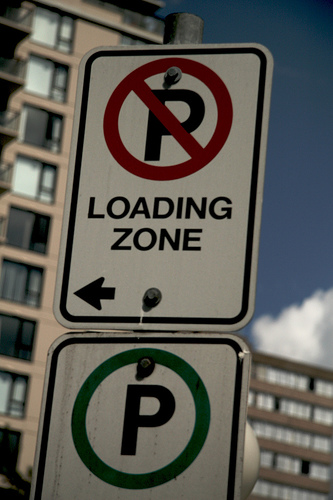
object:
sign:
[25, 318, 265, 500]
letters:
[81, 184, 242, 264]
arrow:
[72, 271, 118, 312]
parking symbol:
[64, 341, 220, 500]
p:
[111, 371, 180, 466]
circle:
[65, 336, 220, 495]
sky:
[155, 1, 333, 380]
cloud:
[242, 283, 333, 373]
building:
[0, 0, 332, 499]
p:
[137, 81, 210, 170]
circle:
[98, 51, 238, 188]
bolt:
[138, 357, 153, 370]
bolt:
[163, 66, 181, 83]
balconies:
[0, 47, 32, 95]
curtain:
[26, 0, 64, 56]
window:
[1, 199, 55, 258]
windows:
[304, 370, 319, 397]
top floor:
[242, 355, 333, 402]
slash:
[135, 81, 210, 166]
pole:
[158, 12, 182, 50]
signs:
[44, 31, 277, 340]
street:
[0, 375, 333, 500]